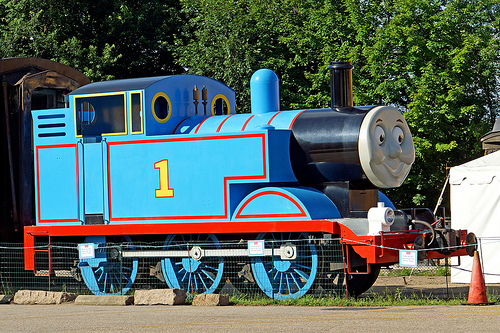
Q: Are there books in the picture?
A: No, there are no books.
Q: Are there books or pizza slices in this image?
A: No, there are no books or pizza slices.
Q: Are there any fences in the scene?
A: Yes, there is a fence.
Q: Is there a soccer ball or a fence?
A: Yes, there is a fence.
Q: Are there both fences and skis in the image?
A: No, there is a fence but no skis.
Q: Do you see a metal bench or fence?
A: Yes, there is a metal fence.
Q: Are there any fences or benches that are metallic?
A: Yes, the fence is metallic.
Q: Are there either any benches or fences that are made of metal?
A: Yes, the fence is made of metal.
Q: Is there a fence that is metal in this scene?
A: Yes, there is a metal fence.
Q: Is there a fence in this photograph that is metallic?
A: Yes, there is a fence that is metallic.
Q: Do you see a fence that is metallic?
A: Yes, there is a fence that is metallic.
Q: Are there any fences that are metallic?
A: Yes, there is a fence that is metallic.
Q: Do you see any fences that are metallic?
A: Yes, there is a fence that is metallic.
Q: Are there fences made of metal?
A: Yes, there is a fence that is made of metal.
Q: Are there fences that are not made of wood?
A: Yes, there is a fence that is made of metal.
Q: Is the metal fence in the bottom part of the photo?
A: Yes, the fence is in the bottom of the image.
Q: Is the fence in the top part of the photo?
A: No, the fence is in the bottom of the image.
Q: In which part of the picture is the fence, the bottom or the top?
A: The fence is in the bottom of the image.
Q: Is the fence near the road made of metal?
A: Yes, the fence is made of metal.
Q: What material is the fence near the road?
A: The fence is made of metal.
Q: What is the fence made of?
A: The fence is made of metal.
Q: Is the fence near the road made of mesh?
A: No, the fence is made of metal.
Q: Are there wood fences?
A: No, there is a fence but it is made of metal.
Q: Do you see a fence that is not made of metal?
A: No, there is a fence but it is made of metal.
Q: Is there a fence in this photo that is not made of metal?
A: No, there is a fence but it is made of metal.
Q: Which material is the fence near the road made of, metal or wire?
A: The fence is made of metal.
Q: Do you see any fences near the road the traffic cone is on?
A: Yes, there is a fence near the road.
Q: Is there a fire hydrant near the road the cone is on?
A: No, there is a fence near the road.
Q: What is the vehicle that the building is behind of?
A: The vehicle is a train.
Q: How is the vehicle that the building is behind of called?
A: The vehicle is a train.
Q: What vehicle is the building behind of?
A: The building is behind the train.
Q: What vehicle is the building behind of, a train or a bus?
A: The building is behind a train.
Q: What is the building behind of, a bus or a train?
A: The building is behind a train.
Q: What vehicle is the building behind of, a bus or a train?
A: The building is behind a train.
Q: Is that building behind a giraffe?
A: No, the building is behind the train.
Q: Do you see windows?
A: Yes, there are windows.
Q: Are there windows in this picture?
A: Yes, there are windows.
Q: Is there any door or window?
A: Yes, there are windows.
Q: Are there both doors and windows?
A: No, there are windows but no doors.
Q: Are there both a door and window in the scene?
A: No, there are windows but no doors.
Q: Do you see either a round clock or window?
A: Yes, there are round windows.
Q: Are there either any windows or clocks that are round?
A: Yes, the windows are round.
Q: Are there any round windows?
A: Yes, there are round windows.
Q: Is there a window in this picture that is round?
A: Yes, there are windows that are round.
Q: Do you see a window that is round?
A: Yes, there are windows that are round.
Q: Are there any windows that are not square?
A: Yes, there are round windows.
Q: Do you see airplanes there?
A: No, there are no airplanes.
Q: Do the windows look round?
A: Yes, the windows are round.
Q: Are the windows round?
A: Yes, the windows are round.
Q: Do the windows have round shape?
A: Yes, the windows are round.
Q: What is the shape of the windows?
A: The windows are round.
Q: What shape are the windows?
A: The windows are round.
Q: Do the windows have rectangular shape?
A: No, the windows are round.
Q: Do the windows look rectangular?
A: No, the windows are round.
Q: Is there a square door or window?
A: No, there are windows but they are round.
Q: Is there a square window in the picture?
A: No, there are windows but they are round.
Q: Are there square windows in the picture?
A: No, there are windows but they are round.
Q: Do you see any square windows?
A: No, there are windows but they are round.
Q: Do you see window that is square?
A: No, there are windows but they are round.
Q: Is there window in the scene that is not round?
A: No, there are windows but they are round.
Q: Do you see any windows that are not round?
A: No, there are windows but they are round.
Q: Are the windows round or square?
A: The windows are round.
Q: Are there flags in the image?
A: No, there are no flags.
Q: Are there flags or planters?
A: No, there are no flags or planters.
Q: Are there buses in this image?
A: No, there are no buses.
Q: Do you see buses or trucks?
A: No, there are no buses or trucks.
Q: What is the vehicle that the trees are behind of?
A: The vehicle is a train.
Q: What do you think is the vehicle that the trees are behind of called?
A: The vehicle is a train.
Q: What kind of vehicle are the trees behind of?
A: The trees are behind the train.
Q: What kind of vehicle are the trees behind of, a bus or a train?
A: The trees are behind a train.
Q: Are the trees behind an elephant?
A: No, the trees are behind the train.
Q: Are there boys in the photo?
A: No, there are no boys.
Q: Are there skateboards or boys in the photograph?
A: No, there are no boys or skateboards.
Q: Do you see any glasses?
A: No, there are no glasses.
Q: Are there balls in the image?
A: No, there are no balls.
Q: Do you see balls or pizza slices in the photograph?
A: No, there are no balls or pizza slices.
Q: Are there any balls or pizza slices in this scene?
A: No, there are no balls or pizza slices.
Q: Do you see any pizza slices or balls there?
A: No, there are no balls or pizza slices.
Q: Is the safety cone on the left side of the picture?
A: No, the safety cone is on the right of the image.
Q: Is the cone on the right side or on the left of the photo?
A: The cone is on the right of the image.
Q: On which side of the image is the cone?
A: The cone is on the right of the image.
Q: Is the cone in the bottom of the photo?
A: Yes, the cone is in the bottom of the image.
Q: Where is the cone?
A: The cone is on the road.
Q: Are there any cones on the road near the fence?
A: Yes, there is a cone on the road.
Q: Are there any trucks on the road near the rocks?
A: No, there is a cone on the road.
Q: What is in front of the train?
A: The cone is in front of the train.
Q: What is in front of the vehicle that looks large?
A: The cone is in front of the train.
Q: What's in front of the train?
A: The cone is in front of the train.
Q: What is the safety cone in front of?
A: The safety cone is in front of the train.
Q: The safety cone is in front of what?
A: The safety cone is in front of the train.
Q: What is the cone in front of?
A: The safety cone is in front of the train.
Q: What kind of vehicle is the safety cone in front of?
A: The safety cone is in front of the train.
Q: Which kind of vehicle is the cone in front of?
A: The safety cone is in front of the train.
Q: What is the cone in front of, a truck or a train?
A: The cone is in front of a train.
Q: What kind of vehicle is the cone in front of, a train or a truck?
A: The cone is in front of a train.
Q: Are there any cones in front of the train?
A: Yes, there is a cone in front of the train.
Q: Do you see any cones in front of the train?
A: Yes, there is a cone in front of the train.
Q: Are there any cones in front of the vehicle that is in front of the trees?
A: Yes, there is a cone in front of the train.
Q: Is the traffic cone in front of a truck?
A: No, the traffic cone is in front of the train.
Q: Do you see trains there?
A: Yes, there is a train.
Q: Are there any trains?
A: Yes, there is a train.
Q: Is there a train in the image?
A: Yes, there is a train.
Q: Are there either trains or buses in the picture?
A: Yes, there is a train.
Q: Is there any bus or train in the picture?
A: Yes, there is a train.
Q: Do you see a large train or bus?
A: Yes, there is a large train.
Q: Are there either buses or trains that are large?
A: Yes, the train is large.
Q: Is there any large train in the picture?
A: Yes, there is a large train.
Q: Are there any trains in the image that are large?
A: Yes, there is a train that is large.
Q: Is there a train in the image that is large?
A: Yes, there is a train that is large.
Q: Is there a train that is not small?
A: Yes, there is a large train.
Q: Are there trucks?
A: No, there are no trucks.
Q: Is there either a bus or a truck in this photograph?
A: No, there are no trucks or buses.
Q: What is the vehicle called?
A: The vehicle is a train.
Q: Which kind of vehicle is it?
A: The vehicle is a train.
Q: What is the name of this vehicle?
A: This is a train.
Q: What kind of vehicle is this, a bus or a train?
A: This is a train.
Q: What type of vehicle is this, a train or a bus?
A: This is a train.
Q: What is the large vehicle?
A: The vehicle is a train.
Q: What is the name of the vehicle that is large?
A: The vehicle is a train.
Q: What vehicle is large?
A: The vehicle is a train.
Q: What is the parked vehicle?
A: The vehicle is a train.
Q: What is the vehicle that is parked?
A: The vehicle is a train.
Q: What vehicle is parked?
A: The vehicle is a train.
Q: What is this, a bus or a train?
A: This is a train.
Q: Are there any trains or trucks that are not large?
A: No, there is a train but it is large.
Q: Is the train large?
A: Yes, the train is large.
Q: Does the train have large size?
A: Yes, the train is large.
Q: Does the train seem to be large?
A: Yes, the train is large.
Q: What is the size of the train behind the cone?
A: The train is large.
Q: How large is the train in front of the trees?
A: The train is large.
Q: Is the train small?
A: No, the train is large.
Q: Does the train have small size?
A: No, the train is large.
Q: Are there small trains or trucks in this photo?
A: No, there is a train but it is large.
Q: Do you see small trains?
A: No, there is a train but it is large.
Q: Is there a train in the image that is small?
A: No, there is a train but it is large.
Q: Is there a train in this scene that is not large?
A: No, there is a train but it is large.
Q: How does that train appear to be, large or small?
A: The train is large.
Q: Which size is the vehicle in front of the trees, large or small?
A: The train is large.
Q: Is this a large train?
A: Yes, this is a large train.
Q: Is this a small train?
A: No, this is a large train.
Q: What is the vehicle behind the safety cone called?
A: The vehicle is a train.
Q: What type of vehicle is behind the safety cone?
A: The vehicle is a train.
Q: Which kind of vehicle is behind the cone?
A: The vehicle is a train.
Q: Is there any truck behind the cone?
A: No, there is a train behind the cone.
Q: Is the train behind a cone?
A: Yes, the train is behind a cone.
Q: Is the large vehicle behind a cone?
A: Yes, the train is behind a cone.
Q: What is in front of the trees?
A: The train is in front of the trees.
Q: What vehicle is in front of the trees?
A: The vehicle is a train.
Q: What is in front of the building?
A: The train is in front of the building.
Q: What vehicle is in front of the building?
A: The vehicle is a train.